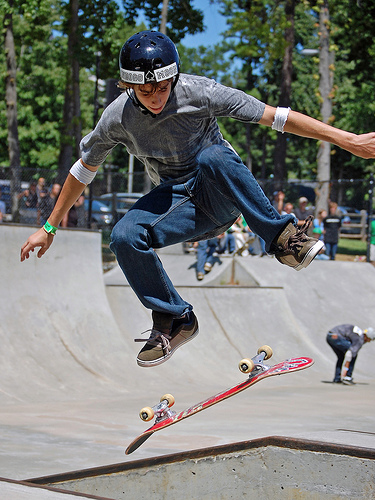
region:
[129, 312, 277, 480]
A skateboard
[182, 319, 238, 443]
A skateboard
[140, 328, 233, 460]
A skateboard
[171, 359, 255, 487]
A skateboard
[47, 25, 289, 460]
boy is doing a trick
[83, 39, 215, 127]
boy is wearing a helmet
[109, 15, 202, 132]
the helmet is blue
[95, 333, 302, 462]
the skateboard is red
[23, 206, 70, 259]
the wristband is green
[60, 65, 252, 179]
the shirt is gray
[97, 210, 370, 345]
the shoes are brown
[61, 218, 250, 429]
the ramp is made of concrete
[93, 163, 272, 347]
the pants are blue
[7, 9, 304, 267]
trees outside the fence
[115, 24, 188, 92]
Boy is wearing protective helmet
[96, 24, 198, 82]
Boy's helmet is dark blue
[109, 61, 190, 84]
Boy's helmet has white trim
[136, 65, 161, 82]
Boys helmet has a spade on the front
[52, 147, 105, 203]
Boy is wearing white band on elbow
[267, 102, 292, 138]
Boy is wearing white band on elbow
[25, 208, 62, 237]
Boy is wearing a green band on his wrist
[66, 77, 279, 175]
Boy is wearing gray T shirt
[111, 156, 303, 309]
Boy is wearing denim pants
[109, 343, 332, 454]
Boy is using a red skateboard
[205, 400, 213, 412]
the skateboard is red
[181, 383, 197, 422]
the skateboard is red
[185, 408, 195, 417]
the skateboard is red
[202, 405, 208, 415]
the skateboard is red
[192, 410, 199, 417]
the skateboard is red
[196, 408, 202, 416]
the skateboard is red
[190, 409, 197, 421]
the skateboard is red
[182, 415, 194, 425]
the skateboard is red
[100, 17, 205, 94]
Young man is wearing a black helmet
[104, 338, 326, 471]
Person is performing a skateboard trick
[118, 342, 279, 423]
Skateboard's wheels are tan colored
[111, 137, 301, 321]
Young man is wearing blue jeans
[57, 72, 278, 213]
Young man is wearing a gray shirt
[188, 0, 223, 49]
The sky is clear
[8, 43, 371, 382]
Young man is in mid air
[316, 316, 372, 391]
Person is in the background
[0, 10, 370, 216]
Tall trees are in the background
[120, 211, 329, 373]
Young man is wearing brown shoes